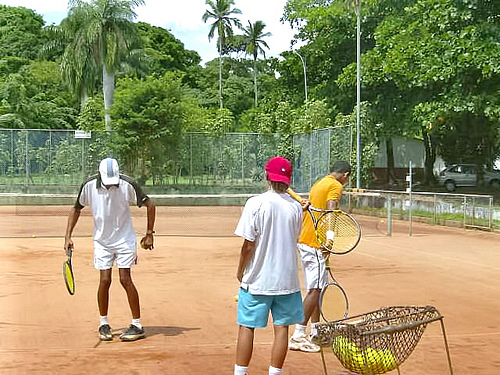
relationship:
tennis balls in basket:
[330, 332, 404, 372] [310, 299, 448, 373]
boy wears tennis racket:
[228, 144, 313, 373] [286, 186, 366, 262]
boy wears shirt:
[293, 154, 356, 361] [301, 175, 348, 247]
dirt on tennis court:
[10, 206, 497, 373] [2, 184, 498, 373]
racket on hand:
[59, 241, 80, 295] [61, 234, 77, 255]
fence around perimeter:
[2, 124, 498, 191] [2, 103, 498, 235]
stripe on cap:
[102, 155, 114, 180] [93, 154, 122, 192]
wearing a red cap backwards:
[251, 155, 296, 200] [269, 147, 298, 173]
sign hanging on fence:
[67, 116, 118, 204] [27, 125, 74, 167]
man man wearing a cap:
[62, 154, 162, 343] [96, 156, 122, 192]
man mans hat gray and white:
[62, 154, 162, 343] [83, 160, 126, 182]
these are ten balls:
[308, 311, 404, 375] [302, 314, 418, 375]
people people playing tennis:
[94, 141, 353, 375] [42, 124, 394, 354]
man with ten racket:
[62, 154, 162, 343] [59, 241, 80, 295]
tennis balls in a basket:
[313, 306, 413, 375] [315, 284, 408, 364]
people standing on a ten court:
[234, 157, 306, 375] [72, 136, 360, 366]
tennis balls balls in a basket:
[352, 348, 388, 374] [306, 285, 402, 375]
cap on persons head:
[261, 156, 296, 187] [263, 116, 306, 175]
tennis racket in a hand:
[55, 236, 78, 361] [65, 230, 118, 339]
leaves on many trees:
[9, 54, 415, 194] [47, 100, 363, 150]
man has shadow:
[62, 154, 162, 343] [92, 320, 202, 351]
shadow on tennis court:
[92, 320, 202, 351] [0, 184, 499, 373]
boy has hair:
[285, 161, 353, 355] [330, 155, 356, 174]